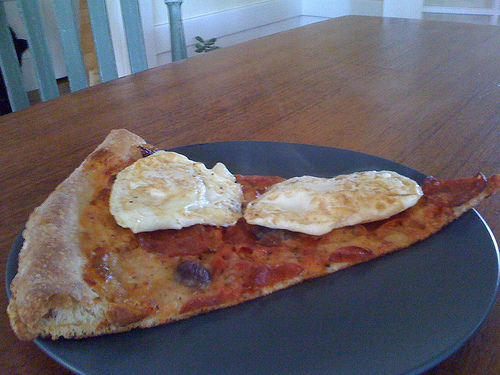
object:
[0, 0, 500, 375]
scene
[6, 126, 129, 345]
crust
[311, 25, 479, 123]
wood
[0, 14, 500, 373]
dining table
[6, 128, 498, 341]
pizza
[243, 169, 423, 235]
egg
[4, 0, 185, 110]
blue chair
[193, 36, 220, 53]
plant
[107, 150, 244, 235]
eggs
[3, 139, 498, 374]
plate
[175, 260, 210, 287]
topping